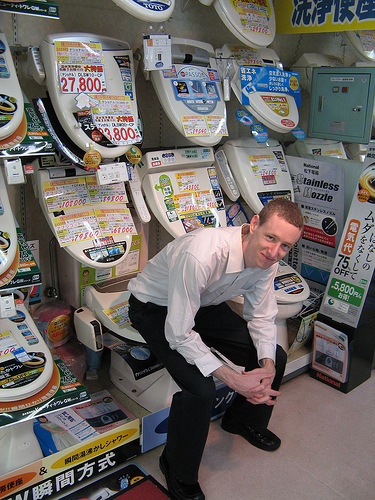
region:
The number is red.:
[112, 126, 121, 141]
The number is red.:
[119, 125, 128, 142]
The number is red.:
[127, 125, 136, 141]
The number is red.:
[92, 76, 101, 91]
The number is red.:
[85, 76, 93, 92]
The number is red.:
[79, 76, 87, 92]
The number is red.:
[67, 75, 77, 92]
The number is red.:
[59, 74, 69, 92]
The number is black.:
[334, 251, 344, 267]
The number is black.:
[341, 255, 351, 270]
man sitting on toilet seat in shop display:
[122, 197, 306, 498]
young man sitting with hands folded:
[115, 197, 315, 498]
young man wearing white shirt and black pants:
[122, 197, 306, 498]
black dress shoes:
[155, 412, 280, 497]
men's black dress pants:
[119, 288, 290, 484]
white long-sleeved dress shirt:
[120, 222, 282, 376]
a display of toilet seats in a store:
[2, 2, 371, 497]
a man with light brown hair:
[125, 195, 305, 497]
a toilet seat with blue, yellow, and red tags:
[210, 41, 305, 139]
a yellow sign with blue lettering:
[271, 0, 372, 42]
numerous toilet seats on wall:
[27, 3, 298, 320]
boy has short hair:
[234, 207, 311, 235]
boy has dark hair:
[241, 191, 304, 237]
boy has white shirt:
[105, 219, 309, 391]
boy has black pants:
[124, 299, 306, 389]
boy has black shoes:
[195, 409, 316, 465]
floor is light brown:
[309, 393, 373, 491]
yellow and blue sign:
[278, 0, 364, 46]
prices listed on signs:
[46, 38, 285, 221]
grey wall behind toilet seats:
[43, 7, 191, 151]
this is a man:
[158, 218, 293, 453]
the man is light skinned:
[230, 374, 272, 393]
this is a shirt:
[168, 231, 217, 280]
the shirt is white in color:
[157, 259, 201, 289]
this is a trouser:
[165, 379, 207, 460]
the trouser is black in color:
[177, 386, 193, 429]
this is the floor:
[285, 422, 338, 495]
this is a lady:
[37, 417, 64, 437]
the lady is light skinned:
[42, 417, 53, 428]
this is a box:
[86, 413, 121, 458]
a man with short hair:
[245, 195, 328, 273]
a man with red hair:
[246, 200, 311, 262]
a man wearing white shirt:
[170, 233, 279, 306]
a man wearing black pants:
[158, 304, 258, 427]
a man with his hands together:
[231, 362, 276, 421]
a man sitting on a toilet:
[90, 201, 293, 381]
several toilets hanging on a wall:
[2, 81, 311, 281]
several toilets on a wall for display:
[10, 66, 292, 230]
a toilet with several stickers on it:
[46, 169, 134, 282]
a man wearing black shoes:
[216, 429, 292, 457]